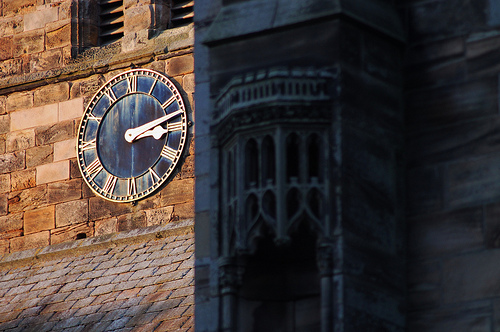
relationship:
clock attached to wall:
[83, 61, 181, 204] [0, 105, 80, 316]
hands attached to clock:
[123, 114, 177, 144] [83, 61, 181, 204]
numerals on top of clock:
[108, 69, 150, 91] [83, 61, 181, 204]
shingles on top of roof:
[161, 284, 185, 308] [1, 236, 193, 326]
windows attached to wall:
[68, 0, 170, 47] [0, 105, 80, 316]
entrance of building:
[244, 244, 321, 324] [39, 90, 474, 321]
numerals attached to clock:
[108, 69, 150, 91] [83, 61, 181, 204]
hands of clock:
[123, 114, 177, 144] [83, 61, 181, 204]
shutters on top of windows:
[75, 6, 132, 41] [68, 0, 170, 47]